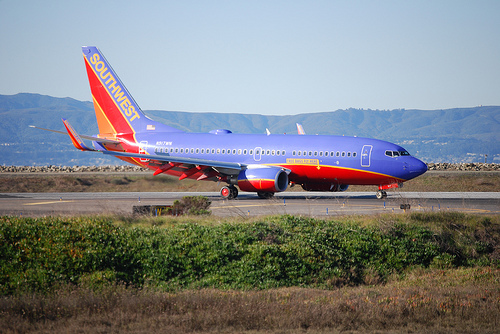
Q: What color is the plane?
A: Blue, red, and orange.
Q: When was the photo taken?
A: Daytime.